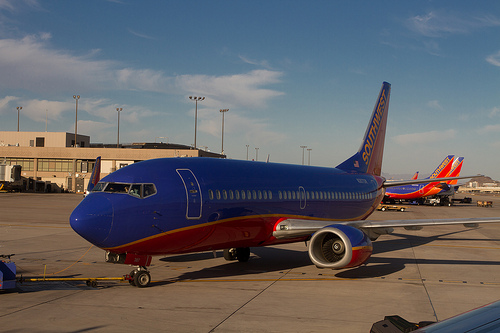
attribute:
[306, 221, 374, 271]
engine — blue, red, yellow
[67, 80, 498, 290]
plane — blue, red, southwest, orange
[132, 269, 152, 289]
wheel — black, white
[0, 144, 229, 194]
building — gray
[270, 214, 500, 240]
wing — silver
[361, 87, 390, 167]
writing — gold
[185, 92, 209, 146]
lightpost — tall